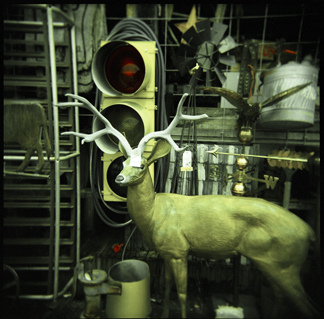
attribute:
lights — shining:
[98, 43, 148, 202]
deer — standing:
[90, 73, 308, 301]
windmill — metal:
[181, 18, 247, 90]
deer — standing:
[88, 103, 315, 273]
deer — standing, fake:
[53, 91, 318, 316]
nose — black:
[114, 171, 122, 181]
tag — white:
[121, 137, 146, 174]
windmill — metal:
[163, 12, 247, 115]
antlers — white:
[52, 93, 208, 156]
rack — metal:
[0, 5, 85, 303]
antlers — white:
[49, 82, 214, 163]